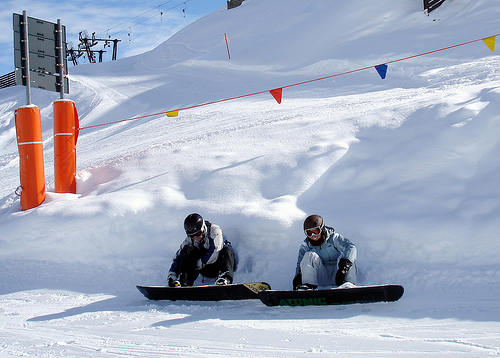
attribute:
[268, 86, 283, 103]
triangle flag — red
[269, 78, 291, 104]
pennant — red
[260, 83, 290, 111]
flag — yellow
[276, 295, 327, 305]
lettering — green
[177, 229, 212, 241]
eyewear — protective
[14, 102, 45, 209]
object — orange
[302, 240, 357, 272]
jacket — blue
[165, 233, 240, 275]
jacket — blue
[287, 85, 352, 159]
wall — triangular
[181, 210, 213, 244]
helmet — black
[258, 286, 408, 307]
snowboard — black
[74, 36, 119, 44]
metal support — metallic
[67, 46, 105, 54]
metal support — metallic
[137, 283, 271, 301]
snowboard — black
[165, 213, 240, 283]
snowboarder — dismounting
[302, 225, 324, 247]
eyewear — protective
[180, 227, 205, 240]
eyewear — protective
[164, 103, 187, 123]
flag — yellow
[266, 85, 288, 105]
flag — green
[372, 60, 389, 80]
flag — red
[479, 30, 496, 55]
flag — yellow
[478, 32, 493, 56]
flag — marking barrier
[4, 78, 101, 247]
supports — orange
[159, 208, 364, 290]
snowboarders — sitting down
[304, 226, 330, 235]
gogles — snow goggles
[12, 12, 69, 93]
sign — back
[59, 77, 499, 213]
hill — ski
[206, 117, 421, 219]
snow bank — small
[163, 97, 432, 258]
ski run — groomed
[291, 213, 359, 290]
snowboarder — dismounting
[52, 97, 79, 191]
object — orange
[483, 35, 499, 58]
flag — yellow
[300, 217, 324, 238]
goggles — orange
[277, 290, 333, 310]
word — Atomic, green